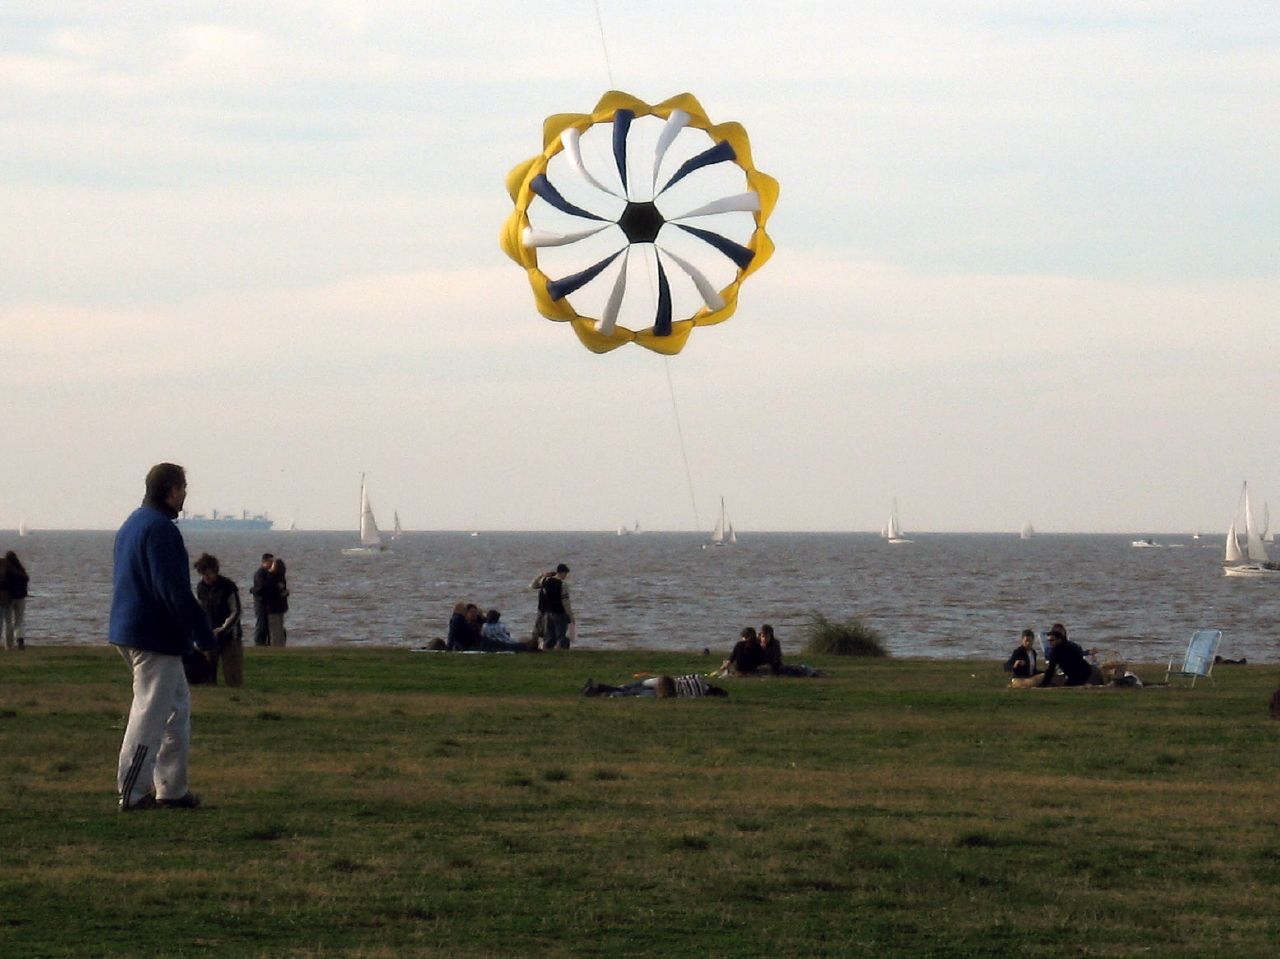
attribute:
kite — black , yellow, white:
[482, 88, 779, 346]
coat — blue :
[112, 502, 209, 655]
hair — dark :
[147, 458, 188, 499]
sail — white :
[1197, 502, 1227, 548]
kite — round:
[512, 76, 777, 350]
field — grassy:
[17, 623, 1236, 913]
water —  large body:
[305, 549, 1154, 644]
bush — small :
[796, 607, 882, 662]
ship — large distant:
[706, 481, 936, 569]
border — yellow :
[494, 83, 796, 352]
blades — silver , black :
[571, 132, 710, 301]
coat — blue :
[108, 505, 212, 660]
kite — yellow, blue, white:
[486, 63, 797, 379]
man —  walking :
[116, 434, 223, 824]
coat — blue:
[108, 507, 201, 665]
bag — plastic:
[187, 591, 235, 663]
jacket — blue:
[110, 500, 210, 660]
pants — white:
[122, 644, 191, 799]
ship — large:
[173, 505, 289, 539]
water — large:
[54, 532, 1217, 692]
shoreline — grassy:
[31, 640, 1229, 942]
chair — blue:
[1164, 626, 1226, 695]